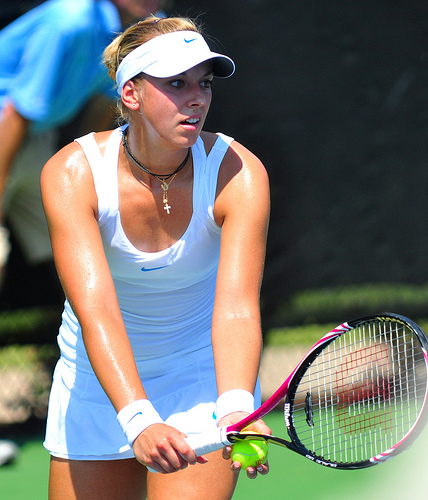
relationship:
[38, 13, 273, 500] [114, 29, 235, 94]
tennis player wears hat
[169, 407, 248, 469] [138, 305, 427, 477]
handle of racket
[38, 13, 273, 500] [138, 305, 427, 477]
tennis player holding racket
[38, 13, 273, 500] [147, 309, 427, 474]
tennis player holding tennis racket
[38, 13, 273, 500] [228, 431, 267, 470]
tennis player holding ball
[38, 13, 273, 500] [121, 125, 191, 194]
tennis player has neck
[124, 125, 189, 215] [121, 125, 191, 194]
necklace around neck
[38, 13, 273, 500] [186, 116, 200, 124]
tennis player has teeth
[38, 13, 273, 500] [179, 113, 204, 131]
tennis player has mouth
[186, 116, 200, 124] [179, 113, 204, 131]
teeth in mouth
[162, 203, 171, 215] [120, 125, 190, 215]
cross on necklace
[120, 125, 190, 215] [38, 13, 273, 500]
necklace of tennis player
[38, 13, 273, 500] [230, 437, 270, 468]
tennis player holding tennis ball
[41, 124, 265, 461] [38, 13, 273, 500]
dress of tennis player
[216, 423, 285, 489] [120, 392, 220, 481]
ball on hand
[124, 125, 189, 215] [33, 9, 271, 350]
necklace on woman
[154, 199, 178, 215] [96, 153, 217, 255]
cross on necklace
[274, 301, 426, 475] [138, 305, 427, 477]
head on racket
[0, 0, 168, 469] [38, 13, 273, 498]
person behind tennis player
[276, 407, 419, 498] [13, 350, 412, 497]
floor of court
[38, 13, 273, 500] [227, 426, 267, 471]
tennis player with ball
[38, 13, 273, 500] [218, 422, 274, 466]
tennis player with ball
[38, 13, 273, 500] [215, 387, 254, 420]
tennis player has sweatband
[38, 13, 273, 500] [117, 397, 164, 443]
tennis player has sweatband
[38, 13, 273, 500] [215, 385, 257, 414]
tennis player has sweatband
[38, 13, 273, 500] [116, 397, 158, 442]
tennis player has sweatband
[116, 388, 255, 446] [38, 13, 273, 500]
sweatbands on tennis player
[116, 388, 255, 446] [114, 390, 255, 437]
sweatbands on wrists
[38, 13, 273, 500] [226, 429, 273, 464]
tennis player holding ball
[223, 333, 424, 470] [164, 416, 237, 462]
racket has tape